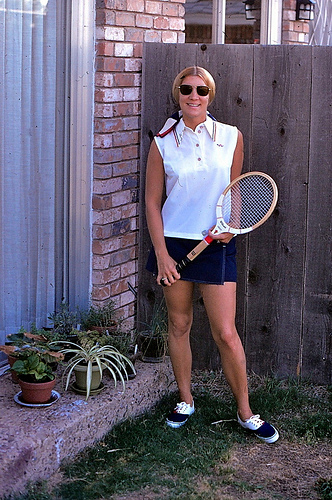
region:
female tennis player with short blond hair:
[144, 65, 278, 442]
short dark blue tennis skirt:
[146, 235, 236, 284]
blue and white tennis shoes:
[164, 400, 278, 442]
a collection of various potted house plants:
[1, 300, 174, 406]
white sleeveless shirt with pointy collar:
[152, 109, 238, 238]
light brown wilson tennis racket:
[159, 170, 277, 284]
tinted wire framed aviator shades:
[177, 84, 210, 96]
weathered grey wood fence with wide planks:
[135, 41, 331, 385]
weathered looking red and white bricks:
[90, 0, 185, 344]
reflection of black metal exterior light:
[241, 0, 259, 19]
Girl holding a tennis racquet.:
[144, 64, 278, 442]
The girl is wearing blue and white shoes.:
[163, 400, 279, 441]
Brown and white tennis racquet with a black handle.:
[154, 169, 275, 285]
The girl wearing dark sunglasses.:
[175, 83, 210, 94]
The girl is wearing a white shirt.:
[151, 112, 234, 235]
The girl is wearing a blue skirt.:
[154, 233, 237, 280]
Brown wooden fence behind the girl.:
[131, 38, 327, 376]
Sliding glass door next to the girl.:
[0, 0, 88, 366]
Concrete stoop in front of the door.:
[0, 351, 180, 497]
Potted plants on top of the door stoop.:
[1, 294, 171, 406]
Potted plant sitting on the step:
[11, 356, 62, 407]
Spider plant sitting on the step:
[51, 339, 134, 403]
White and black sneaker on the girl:
[163, 401, 195, 424]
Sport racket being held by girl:
[157, 171, 277, 286]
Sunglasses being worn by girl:
[177, 83, 211, 97]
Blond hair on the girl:
[170, 64, 214, 103]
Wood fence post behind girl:
[241, 44, 319, 386]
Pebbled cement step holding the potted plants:
[1, 408, 72, 462]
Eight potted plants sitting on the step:
[5, 304, 169, 399]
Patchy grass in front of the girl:
[115, 433, 297, 499]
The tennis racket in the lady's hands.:
[157, 170, 276, 279]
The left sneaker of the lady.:
[169, 400, 195, 426]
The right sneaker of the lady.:
[231, 413, 277, 443]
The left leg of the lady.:
[165, 282, 198, 404]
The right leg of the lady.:
[209, 280, 255, 418]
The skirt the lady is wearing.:
[147, 237, 235, 285]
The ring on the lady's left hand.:
[159, 276, 165, 281]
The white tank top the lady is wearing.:
[155, 127, 231, 241]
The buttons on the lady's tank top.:
[189, 124, 206, 165]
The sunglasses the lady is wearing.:
[178, 84, 208, 97]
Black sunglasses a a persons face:
[179, 85, 206, 95]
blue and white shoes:
[179, 392, 196, 426]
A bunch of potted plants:
[11, 320, 134, 373]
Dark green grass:
[112, 427, 204, 471]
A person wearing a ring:
[149, 246, 188, 287]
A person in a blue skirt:
[148, 231, 243, 281]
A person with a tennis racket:
[154, 170, 283, 284]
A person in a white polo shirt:
[159, 113, 246, 238]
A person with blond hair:
[166, 60, 214, 108]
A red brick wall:
[100, 19, 142, 148]